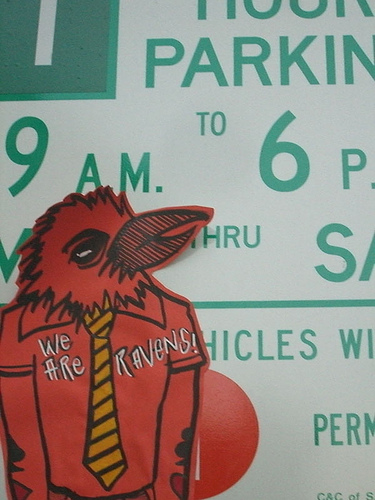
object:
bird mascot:
[1, 182, 215, 497]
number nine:
[5, 114, 49, 197]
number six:
[258, 109, 311, 192]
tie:
[82, 294, 128, 490]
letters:
[210, 111, 227, 137]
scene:
[0, 0, 374, 497]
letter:
[145, 36, 185, 88]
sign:
[0, 0, 374, 497]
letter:
[313, 412, 328, 446]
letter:
[346, 411, 362, 444]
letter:
[233, 328, 253, 360]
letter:
[256, 327, 274, 360]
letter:
[299, 327, 318, 359]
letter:
[338, 326, 363, 359]